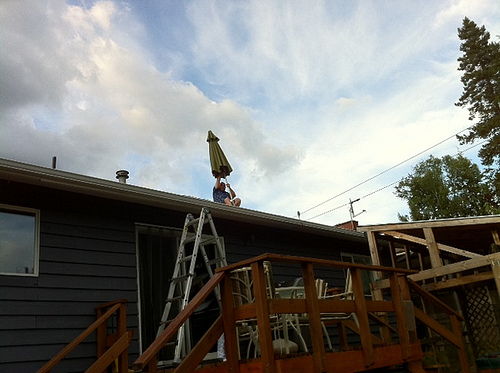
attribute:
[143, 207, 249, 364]
ladder — stainless, metal, large, silver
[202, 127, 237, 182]
umbrella — green, large, closed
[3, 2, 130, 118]
clouds — white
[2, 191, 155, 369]
wall — painted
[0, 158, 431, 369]
house — gray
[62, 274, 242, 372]
stairs — wood, wooden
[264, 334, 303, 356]
box — white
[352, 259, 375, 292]
curtain — white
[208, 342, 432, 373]
floor — wooden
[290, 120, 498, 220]
wires — eletric, long, electrical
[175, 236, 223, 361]
door — glass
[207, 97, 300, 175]
cloud — white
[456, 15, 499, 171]
tree — green, tall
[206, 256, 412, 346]
railing — wood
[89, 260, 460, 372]
deck — wooden, red